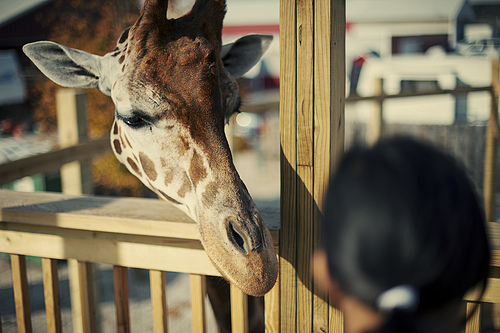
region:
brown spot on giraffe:
[110, 122, 121, 135]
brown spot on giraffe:
[111, 138, 120, 153]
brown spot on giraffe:
[118, 136, 125, 148]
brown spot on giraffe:
[122, 130, 132, 150]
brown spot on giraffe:
[122, 154, 143, 179]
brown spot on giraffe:
[136, 150, 159, 179]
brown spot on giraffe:
[162, 160, 177, 185]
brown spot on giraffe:
[176, 170, 192, 200]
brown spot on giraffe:
[183, 148, 208, 193]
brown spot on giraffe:
[170, 132, 187, 157]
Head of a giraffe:
[21, 2, 304, 319]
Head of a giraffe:
[21, 5, 299, 322]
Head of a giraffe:
[11, 1, 291, 301]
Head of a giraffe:
[16, 0, 298, 325]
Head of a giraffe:
[12, 0, 312, 297]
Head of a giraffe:
[16, 1, 300, 316]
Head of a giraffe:
[21, 0, 312, 325]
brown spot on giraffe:
[108, 124, 124, 141]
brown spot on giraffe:
[122, 153, 144, 174]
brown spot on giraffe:
[131, 149, 138, 164]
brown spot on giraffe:
[135, 149, 160, 184]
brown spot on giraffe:
[160, 168, 175, 185]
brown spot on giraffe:
[172, 171, 192, 205]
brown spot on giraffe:
[183, 144, 208, 189]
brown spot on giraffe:
[117, 51, 127, 68]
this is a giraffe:
[28, 7, 321, 322]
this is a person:
[268, 81, 495, 331]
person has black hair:
[294, 115, 489, 330]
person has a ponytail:
[293, 108, 496, 330]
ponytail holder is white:
[338, 262, 443, 319]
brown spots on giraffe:
[120, 145, 227, 201]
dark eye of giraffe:
[110, 90, 162, 139]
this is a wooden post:
[252, 5, 342, 331]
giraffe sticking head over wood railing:
[37, 0, 316, 332]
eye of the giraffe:
[116, 108, 173, 138]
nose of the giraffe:
[205, 201, 270, 256]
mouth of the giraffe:
[214, 285, 260, 300]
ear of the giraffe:
[29, 56, 111, 90]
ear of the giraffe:
[220, 15, 273, 87]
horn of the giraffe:
[192, 0, 220, 41]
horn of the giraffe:
[143, 5, 163, 39]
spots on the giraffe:
[165, 149, 230, 200]